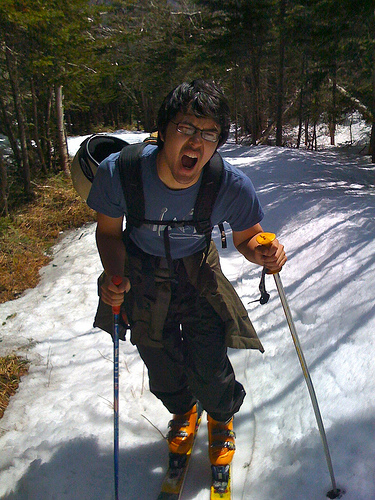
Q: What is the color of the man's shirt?
A: Blue.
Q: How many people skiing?
A: One.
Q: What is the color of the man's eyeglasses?
A: Black.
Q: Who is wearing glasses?
A: A man.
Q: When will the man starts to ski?
A: Later.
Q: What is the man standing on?
A: Ski board.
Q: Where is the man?
A: On the snow.